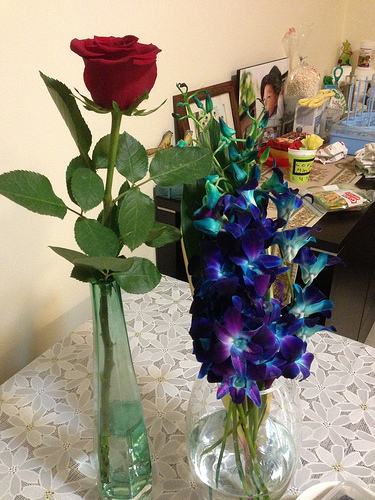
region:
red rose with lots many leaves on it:
[0, 26, 214, 498]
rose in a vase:
[0, 30, 213, 497]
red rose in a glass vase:
[0, 30, 216, 493]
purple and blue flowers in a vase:
[188, 94, 346, 496]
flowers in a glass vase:
[188, 86, 337, 499]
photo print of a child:
[237, 64, 298, 144]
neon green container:
[290, 144, 315, 184]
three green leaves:
[115, 133, 213, 242]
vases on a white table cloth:
[3, 274, 372, 499]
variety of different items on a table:
[160, 30, 372, 236]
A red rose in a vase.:
[49, 11, 169, 126]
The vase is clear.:
[75, 282, 159, 496]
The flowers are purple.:
[176, 109, 320, 390]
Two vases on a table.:
[30, 246, 350, 494]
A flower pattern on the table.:
[7, 401, 79, 495]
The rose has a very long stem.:
[90, 112, 124, 496]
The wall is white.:
[159, 7, 252, 49]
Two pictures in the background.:
[156, 43, 311, 175]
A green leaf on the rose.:
[1, 158, 66, 230]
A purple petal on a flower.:
[242, 378, 266, 411]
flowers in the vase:
[48, 34, 312, 479]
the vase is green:
[75, 271, 176, 498]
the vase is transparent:
[184, 361, 322, 493]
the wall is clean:
[7, 17, 82, 223]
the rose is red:
[42, 49, 166, 158]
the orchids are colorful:
[167, 72, 329, 408]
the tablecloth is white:
[13, 331, 156, 496]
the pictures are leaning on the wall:
[162, 41, 361, 217]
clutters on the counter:
[264, 119, 374, 230]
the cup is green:
[283, 128, 328, 197]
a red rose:
[67, 28, 165, 114]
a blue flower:
[293, 244, 348, 284]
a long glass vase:
[82, 274, 159, 495]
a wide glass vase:
[165, 350, 299, 498]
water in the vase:
[92, 398, 157, 498]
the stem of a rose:
[96, 283, 117, 490]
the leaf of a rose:
[0, 164, 70, 222]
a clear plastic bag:
[296, 177, 368, 219]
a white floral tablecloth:
[0, 268, 373, 498]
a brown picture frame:
[171, 80, 245, 155]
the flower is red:
[58, 17, 258, 181]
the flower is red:
[66, 28, 196, 135]